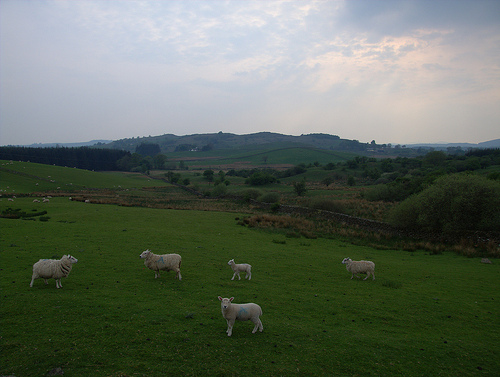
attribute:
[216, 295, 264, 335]
sheep — five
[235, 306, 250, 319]
marked — blue